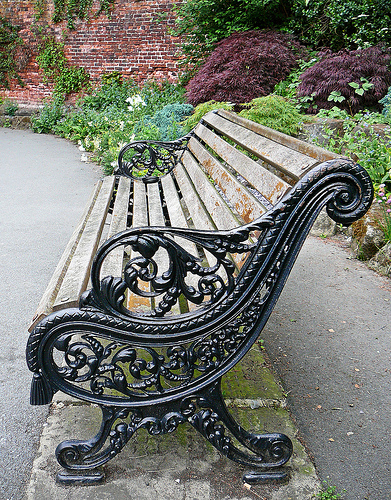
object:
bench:
[25, 109, 374, 487]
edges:
[26, 109, 373, 485]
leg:
[54, 404, 138, 486]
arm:
[79, 218, 267, 322]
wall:
[0, 0, 207, 110]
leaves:
[184, 26, 390, 116]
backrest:
[163, 107, 373, 336]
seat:
[28, 173, 218, 351]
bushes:
[33, 0, 390, 253]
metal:
[27, 109, 374, 487]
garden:
[1, 0, 390, 473]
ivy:
[0, 0, 390, 136]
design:
[26, 107, 373, 484]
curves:
[25, 107, 374, 486]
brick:
[0, 0, 208, 110]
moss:
[93, 252, 313, 469]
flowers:
[79, 90, 148, 174]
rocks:
[308, 194, 390, 278]